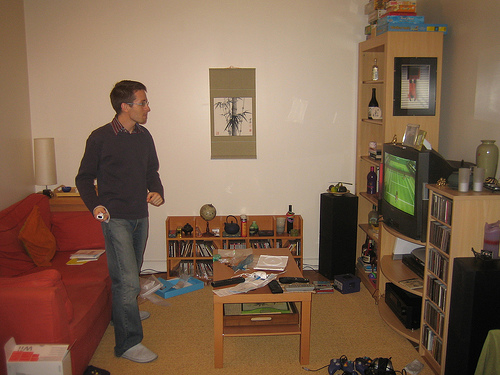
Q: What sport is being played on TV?
A: Tennis.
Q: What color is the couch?
A: Orange.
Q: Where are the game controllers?
A: On the floor in front of the media storage unit.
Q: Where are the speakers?
A: In front of the bookshelves and to the right of the media storage unit.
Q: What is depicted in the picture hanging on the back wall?
A: A bamboo shoot.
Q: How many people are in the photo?
A: One.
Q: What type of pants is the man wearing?
A: Jeans.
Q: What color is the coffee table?
A: Brown.